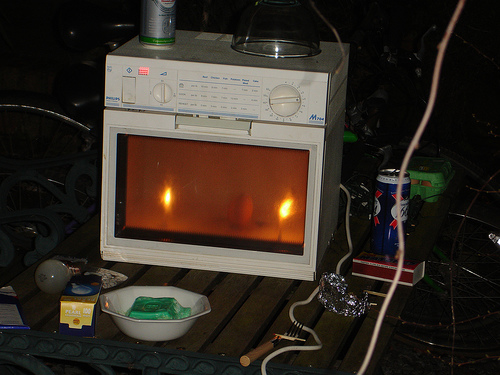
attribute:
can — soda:
[365, 174, 440, 256]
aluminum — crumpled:
[310, 264, 384, 330]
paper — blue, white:
[3, 283, 37, 332]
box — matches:
[349, 249, 425, 287]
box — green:
[401, 150, 456, 206]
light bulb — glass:
[33, 256, 80, 294]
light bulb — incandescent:
[30, 262, 76, 297]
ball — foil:
[315, 270, 365, 320]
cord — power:
[303, 185, 425, 357]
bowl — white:
[97, 283, 211, 343]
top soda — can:
[372, 165, 415, 189]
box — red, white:
[349, 229, 461, 304]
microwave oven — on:
[93, 25, 355, 287]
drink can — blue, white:
[354, 152, 432, 265]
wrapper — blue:
[1, 279, 46, 362]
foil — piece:
[316, 272, 371, 317]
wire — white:
[384, 71, 459, 168]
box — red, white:
[338, 251, 429, 286]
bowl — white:
[85, 247, 218, 346]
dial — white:
[268, 85, 301, 117]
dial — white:
[152, 81, 173, 101]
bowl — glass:
[227, 2, 322, 62]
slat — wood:
[287, 151, 435, 371]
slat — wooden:
[79, 260, 182, 340]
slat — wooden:
[117, 270, 221, 350]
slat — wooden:
[156, 272, 259, 354]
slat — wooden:
[15, 232, 112, 330]